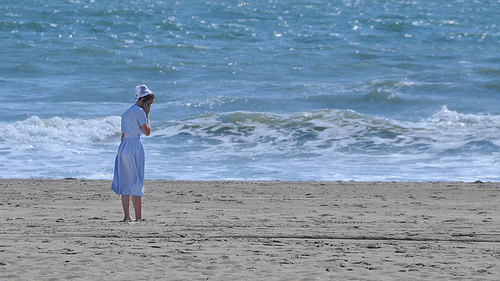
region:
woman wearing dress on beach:
[108, 76, 162, 198]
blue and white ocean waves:
[10, 6, 44, 38]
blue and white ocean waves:
[204, 26, 257, 83]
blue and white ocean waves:
[256, 97, 284, 138]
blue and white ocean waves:
[310, 89, 346, 125]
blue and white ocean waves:
[379, 137, 423, 179]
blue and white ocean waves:
[329, 48, 370, 74]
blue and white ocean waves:
[17, 109, 52, 148]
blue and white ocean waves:
[67, 7, 112, 54]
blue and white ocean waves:
[282, 31, 330, 85]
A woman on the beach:
[111, 78, 155, 224]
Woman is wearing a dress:
[111, 84, 156, 219]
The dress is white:
[113, 102, 153, 201]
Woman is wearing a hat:
[130, 77, 156, 110]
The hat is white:
[133, 82, 152, 101]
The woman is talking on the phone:
[111, 84, 156, 224]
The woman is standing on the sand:
[111, 80, 160, 225]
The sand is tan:
[5, 174, 491, 278]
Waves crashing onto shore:
[28, 75, 474, 162]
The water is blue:
[112, 13, 399, 79]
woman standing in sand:
[101, 80, 172, 245]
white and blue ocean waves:
[17, 18, 45, 52]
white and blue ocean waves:
[268, 59, 304, 103]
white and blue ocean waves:
[252, 65, 301, 130]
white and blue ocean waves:
[308, 105, 352, 152]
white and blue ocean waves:
[376, 111, 422, 147]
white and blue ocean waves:
[201, 62, 259, 101]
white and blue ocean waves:
[36, 110, 88, 157]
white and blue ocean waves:
[44, 32, 72, 57]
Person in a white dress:
[104, 79, 168, 230]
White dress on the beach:
[108, 79, 162, 239]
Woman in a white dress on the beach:
[102, 76, 169, 234]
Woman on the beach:
[1, 11, 492, 275]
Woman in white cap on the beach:
[95, 69, 182, 259]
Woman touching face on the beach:
[108, 68, 163, 235]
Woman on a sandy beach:
[1, 8, 485, 260]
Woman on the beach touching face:
[7, 8, 485, 273]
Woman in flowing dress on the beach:
[110, 78, 167, 235]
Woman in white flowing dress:
[101, 76, 161, 233]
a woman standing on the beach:
[112, 81, 152, 218]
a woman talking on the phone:
[109, 82, 154, 219]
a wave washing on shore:
[3, 98, 495, 150]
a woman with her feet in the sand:
[114, 81, 156, 225]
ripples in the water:
[93, 6, 440, 62]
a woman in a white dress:
[109, 83, 155, 220]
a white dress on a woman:
[105, 83, 154, 223]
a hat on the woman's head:
[113, 84, 155, 107]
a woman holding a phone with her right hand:
[122, 83, 152, 114]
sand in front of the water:
[0, 178, 495, 278]